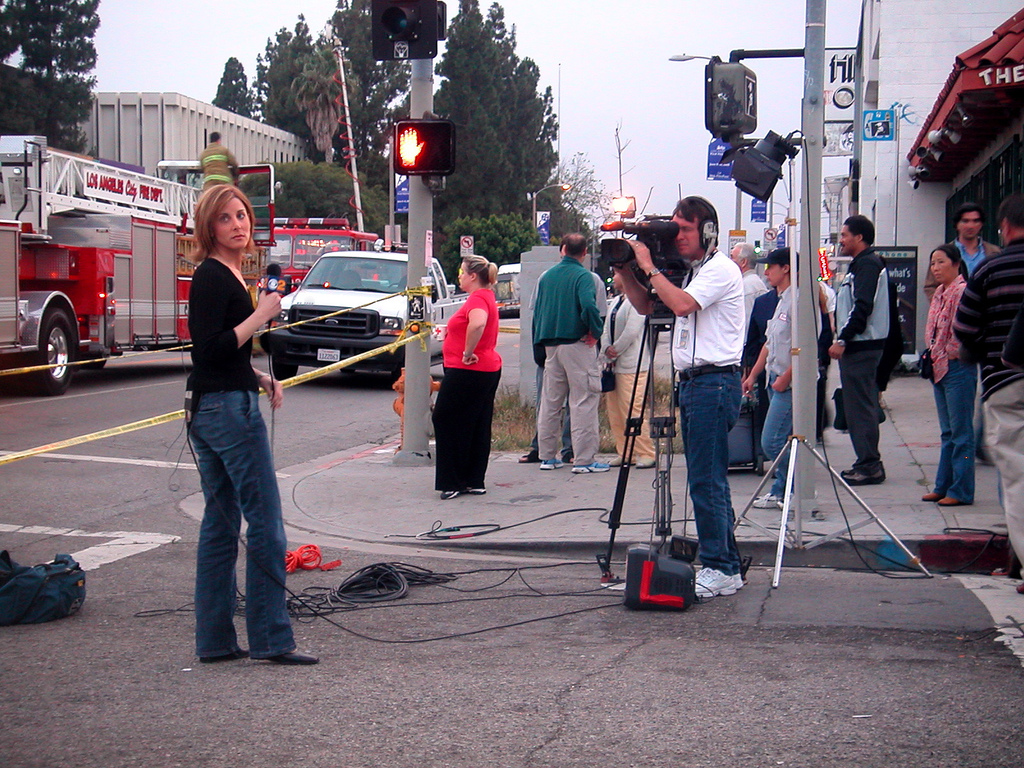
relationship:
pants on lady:
[153, 389, 337, 677] [170, 166, 331, 681]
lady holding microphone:
[187, 184, 322, 667] [258, 256, 284, 298]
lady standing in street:
[187, 184, 322, 667] [3, 502, 993, 760]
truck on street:
[255, 184, 457, 373] [85, 351, 926, 725]